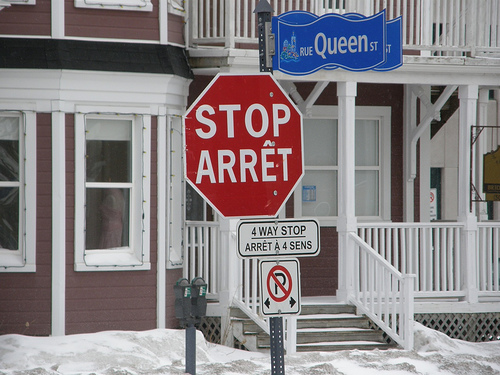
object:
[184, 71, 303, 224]
stop sign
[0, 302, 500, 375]
snow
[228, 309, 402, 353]
steps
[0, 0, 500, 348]
building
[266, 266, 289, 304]
circle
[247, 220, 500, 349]
railing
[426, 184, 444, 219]
sign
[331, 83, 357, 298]
post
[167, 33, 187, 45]
bricks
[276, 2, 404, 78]
sign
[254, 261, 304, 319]
no parking sign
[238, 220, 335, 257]
4-way stop sign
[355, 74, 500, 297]
porch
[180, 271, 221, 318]
parking meters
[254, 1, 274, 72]
signpole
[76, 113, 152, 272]
window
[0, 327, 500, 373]
ground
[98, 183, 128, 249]
dress